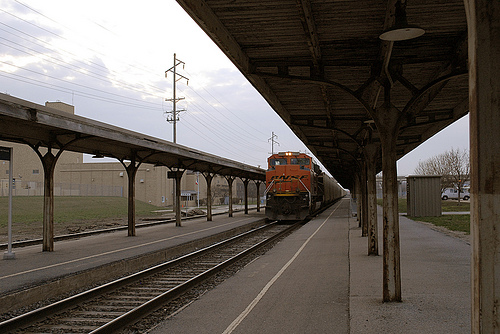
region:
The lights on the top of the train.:
[285, 148, 297, 158]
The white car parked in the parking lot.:
[440, 177, 472, 201]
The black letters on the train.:
[271, 173, 313, 181]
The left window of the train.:
[269, 158, 285, 164]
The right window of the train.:
[289, 153, 309, 165]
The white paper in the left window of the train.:
[274, 159, 281, 166]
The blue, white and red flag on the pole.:
[190, 175, 200, 206]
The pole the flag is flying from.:
[194, 169, 206, 209]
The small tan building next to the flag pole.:
[179, 177, 199, 206]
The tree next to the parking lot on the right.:
[417, 145, 467, 202]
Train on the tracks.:
[246, 115, 378, 272]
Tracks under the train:
[206, 184, 353, 278]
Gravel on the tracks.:
[170, 213, 281, 299]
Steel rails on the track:
[171, 213, 338, 329]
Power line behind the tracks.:
[158, 67, 200, 170]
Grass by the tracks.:
[49, 152, 209, 239]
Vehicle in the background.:
[431, 170, 484, 220]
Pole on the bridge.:
[105, 127, 166, 246]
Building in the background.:
[41, 146, 210, 243]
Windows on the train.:
[270, 148, 307, 223]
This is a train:
[265, 151, 349, 237]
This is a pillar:
[37, 148, 69, 265]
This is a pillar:
[118, 160, 148, 248]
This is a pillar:
[165, 168, 187, 234]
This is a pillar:
[198, 172, 222, 226]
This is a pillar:
[222, 176, 240, 220]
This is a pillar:
[238, 177, 251, 220]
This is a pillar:
[251, 175, 261, 217]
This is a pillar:
[378, 122, 403, 311]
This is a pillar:
[359, 138, 379, 269]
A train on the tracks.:
[248, 133, 354, 239]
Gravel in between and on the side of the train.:
[111, 235, 261, 305]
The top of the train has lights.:
[275, 140, 295, 160]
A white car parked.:
[437, 170, 472, 210]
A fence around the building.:
[46, 160, 161, 205]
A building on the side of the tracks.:
[1, 126, 161, 201]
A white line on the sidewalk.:
[266, 222, 301, 312]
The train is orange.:
[245, 151, 340, 236]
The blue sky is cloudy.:
[45, 20, 205, 130]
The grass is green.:
[29, 184, 130, 221]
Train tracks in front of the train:
[193, 224, 249, 272]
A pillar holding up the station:
[378, 125, 404, 292]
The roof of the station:
[30, 100, 192, 156]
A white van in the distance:
[444, 185, 471, 199]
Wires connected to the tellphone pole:
[46, 72, 164, 114]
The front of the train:
[271, 151, 311, 221]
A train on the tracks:
[268, 155, 340, 212]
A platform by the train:
[331, 210, 368, 322]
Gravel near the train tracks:
[200, 281, 214, 288]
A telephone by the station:
[168, 60, 182, 142]